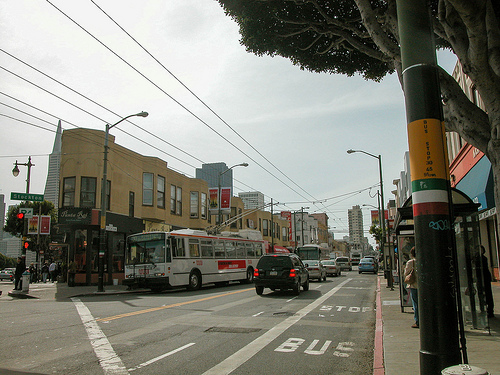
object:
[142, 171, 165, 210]
windows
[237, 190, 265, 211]
building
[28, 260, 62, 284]
people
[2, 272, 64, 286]
sidewalk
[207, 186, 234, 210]
banners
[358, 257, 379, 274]
vehicle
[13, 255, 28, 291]
player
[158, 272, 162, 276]
headlights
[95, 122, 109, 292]
pole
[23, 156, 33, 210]
pole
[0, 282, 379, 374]
ground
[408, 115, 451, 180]
patch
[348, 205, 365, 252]
building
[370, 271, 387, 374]
curb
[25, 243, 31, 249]
walk light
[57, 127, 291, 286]
building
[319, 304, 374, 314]
stop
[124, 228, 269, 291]
bus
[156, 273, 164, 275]
headlight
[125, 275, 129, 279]
headlight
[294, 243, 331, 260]
bus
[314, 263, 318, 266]
headlight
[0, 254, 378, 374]
street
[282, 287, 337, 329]
line part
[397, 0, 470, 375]
pole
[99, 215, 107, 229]
yellow patch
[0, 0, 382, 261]
wires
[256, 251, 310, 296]
suv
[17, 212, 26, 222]
traffic light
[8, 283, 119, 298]
corner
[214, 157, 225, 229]
pole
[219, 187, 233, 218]
patch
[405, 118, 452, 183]
square patch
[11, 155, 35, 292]
light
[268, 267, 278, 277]
license plate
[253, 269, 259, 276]
light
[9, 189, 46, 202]
sign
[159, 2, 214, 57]
cloud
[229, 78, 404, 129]
cloud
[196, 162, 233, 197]
building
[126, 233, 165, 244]
marquee display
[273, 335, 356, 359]
word bus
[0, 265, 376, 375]
road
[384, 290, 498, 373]
sidewalk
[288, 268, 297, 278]
brake light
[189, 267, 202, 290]
wheel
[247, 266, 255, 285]
wheel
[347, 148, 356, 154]
streetlight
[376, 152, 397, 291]
pole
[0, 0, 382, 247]
power